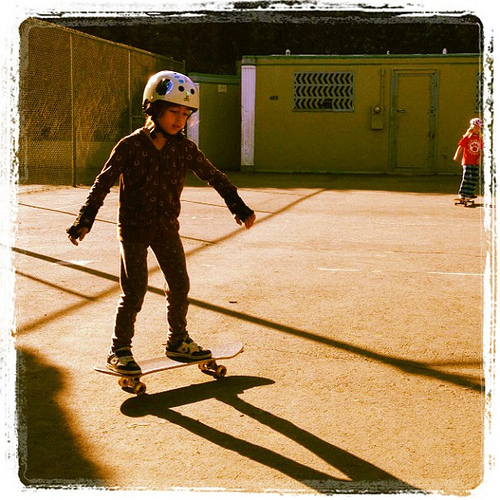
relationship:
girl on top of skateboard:
[69, 69, 255, 376] [97, 342, 248, 396]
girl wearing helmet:
[69, 69, 255, 376] [143, 70, 198, 115]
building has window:
[186, 54, 485, 179] [294, 73, 354, 113]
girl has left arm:
[69, 69, 255, 376] [183, 140, 256, 230]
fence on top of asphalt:
[18, 25, 188, 186] [19, 174, 482, 490]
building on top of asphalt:
[186, 54, 485, 179] [19, 174, 482, 490]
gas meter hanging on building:
[369, 67, 385, 131] [186, 54, 485, 179]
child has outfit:
[453, 117, 486, 207] [459, 133, 482, 197]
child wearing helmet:
[453, 117, 486, 207] [467, 118, 480, 130]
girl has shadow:
[69, 69, 255, 376] [122, 375, 429, 499]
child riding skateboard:
[453, 117, 486, 207] [456, 198, 477, 207]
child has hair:
[453, 117, 486, 207] [468, 125, 484, 141]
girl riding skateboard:
[69, 69, 255, 376] [97, 342, 248, 396]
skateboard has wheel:
[97, 342, 248, 396] [216, 364, 228, 379]